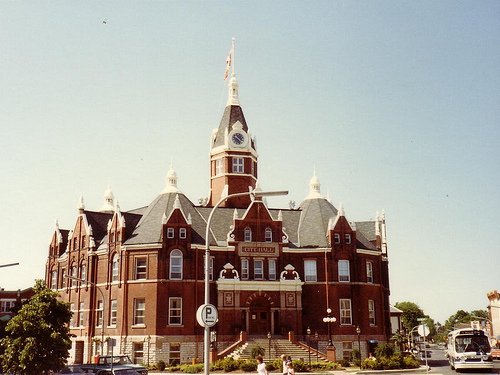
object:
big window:
[169, 249, 183, 281]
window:
[169, 346, 180, 365]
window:
[133, 342, 143, 364]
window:
[166, 228, 185, 238]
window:
[243, 228, 271, 243]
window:
[368, 300, 375, 327]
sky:
[0, 0, 500, 327]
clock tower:
[209, 37, 257, 157]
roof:
[123, 193, 163, 244]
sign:
[238, 242, 279, 257]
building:
[486, 289, 500, 359]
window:
[133, 298, 145, 325]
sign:
[471, 321, 480, 328]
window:
[304, 259, 317, 282]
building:
[44, 38, 392, 367]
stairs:
[217, 338, 334, 363]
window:
[338, 260, 350, 283]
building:
[389, 304, 404, 366]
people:
[280, 354, 295, 375]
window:
[268, 259, 277, 280]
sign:
[417, 325, 430, 337]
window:
[135, 258, 147, 280]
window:
[366, 262, 373, 283]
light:
[196, 189, 289, 375]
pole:
[204, 191, 251, 304]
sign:
[196, 304, 219, 327]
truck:
[71, 356, 147, 375]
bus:
[444, 327, 494, 372]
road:
[416, 344, 500, 375]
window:
[110, 299, 117, 325]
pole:
[101, 297, 104, 361]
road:
[71, 364, 499, 375]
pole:
[267, 331, 271, 363]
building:
[0, 287, 34, 375]